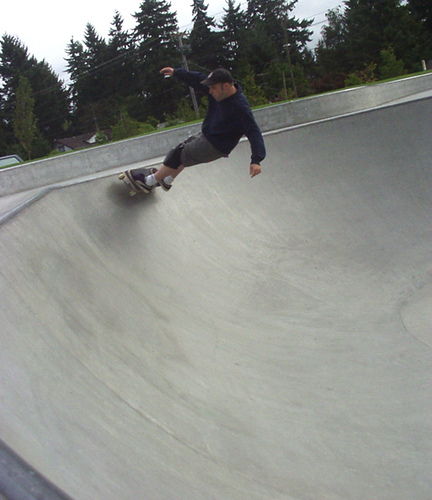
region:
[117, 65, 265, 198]
man riding on a skateboard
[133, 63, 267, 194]
man wearing a blue sweatshirt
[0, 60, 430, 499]
man skating in a skate park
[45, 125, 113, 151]
brown roof of a house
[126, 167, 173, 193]
burgundy shoes with tan soles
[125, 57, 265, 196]
man wearing a hat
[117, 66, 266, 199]
man wearing black knee pads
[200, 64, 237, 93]
Hat on a man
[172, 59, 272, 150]
Sweatshirt on a man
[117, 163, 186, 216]
Skateboard under a man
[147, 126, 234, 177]
Shorts on a man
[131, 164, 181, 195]
Shoes on a man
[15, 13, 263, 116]
Trees by a skatepark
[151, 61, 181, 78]
Hand in the air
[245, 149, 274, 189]
Hand pointing down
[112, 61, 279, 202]
Man skateboarding in a bowl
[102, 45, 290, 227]
the man is skateboarding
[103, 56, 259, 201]
the man is skateboarding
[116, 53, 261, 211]
the man is skateboarding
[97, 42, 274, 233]
the man is skateboarding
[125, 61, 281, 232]
the man is skateboarding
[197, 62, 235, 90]
the cap is black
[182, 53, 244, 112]
the cap is black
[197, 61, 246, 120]
the cap is black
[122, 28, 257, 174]
this is a man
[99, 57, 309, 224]
the man is skating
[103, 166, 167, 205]
this is a skate board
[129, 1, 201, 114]
this is a tree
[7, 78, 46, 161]
this is a tree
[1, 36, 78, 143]
this is a tree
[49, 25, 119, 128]
this is a tree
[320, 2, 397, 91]
this is a tree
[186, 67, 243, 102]
the man is in a black cape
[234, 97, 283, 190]
this is a hand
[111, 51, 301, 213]
the man is skating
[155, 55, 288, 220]
this is a man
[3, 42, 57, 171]
this is a tree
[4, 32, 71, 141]
this is a tree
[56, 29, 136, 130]
this is a tree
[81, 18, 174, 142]
this is a tree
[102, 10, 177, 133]
this is a tree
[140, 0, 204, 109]
this is a tree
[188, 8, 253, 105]
this is a tree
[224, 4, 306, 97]
this is a tree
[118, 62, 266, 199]
person is skateboarding bowl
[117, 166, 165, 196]
black grip on skateboard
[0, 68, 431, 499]
person is skating in skatepark